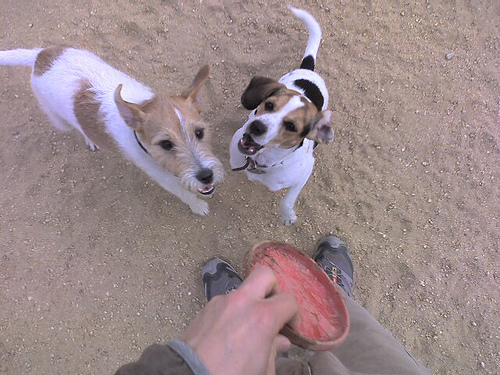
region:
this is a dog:
[200, 0, 360, 232]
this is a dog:
[3, 38, 238, 230]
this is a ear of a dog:
[308, 119, 344, 150]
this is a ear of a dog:
[228, 65, 280, 111]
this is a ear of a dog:
[171, 65, 228, 108]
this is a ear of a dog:
[103, 84, 150, 134]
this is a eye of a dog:
[188, 119, 212, 141]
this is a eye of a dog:
[150, 113, 182, 165]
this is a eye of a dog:
[283, 117, 298, 146]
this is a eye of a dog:
[262, 101, 279, 113]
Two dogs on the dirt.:
[1, 24, 336, 225]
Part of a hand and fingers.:
[175, 263, 300, 374]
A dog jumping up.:
[227, 4, 341, 228]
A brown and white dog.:
[1, 43, 228, 216]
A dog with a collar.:
[229, 5, 341, 227]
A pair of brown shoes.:
[200, 235, 355, 306]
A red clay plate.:
[239, 237, 351, 351]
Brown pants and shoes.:
[198, 235, 430, 374]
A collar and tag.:
[232, 155, 267, 175]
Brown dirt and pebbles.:
[3, 2, 498, 371]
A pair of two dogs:
[1, 5, 335, 226]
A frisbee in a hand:
[175, 239, 352, 373]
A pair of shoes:
[200, 231, 357, 304]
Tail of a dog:
[284, 2, 325, 67]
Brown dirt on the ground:
[1, 0, 498, 373]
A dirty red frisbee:
[243, 238, 352, 353]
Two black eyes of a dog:
[157, 123, 210, 154]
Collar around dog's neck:
[230, 136, 309, 180]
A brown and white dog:
[0, 41, 226, 220]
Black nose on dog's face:
[244, 111, 269, 141]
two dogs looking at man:
[30, 41, 344, 214]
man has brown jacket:
[140, 332, 204, 367]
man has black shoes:
[303, 224, 365, 291]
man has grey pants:
[337, 285, 432, 372]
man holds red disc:
[262, 238, 389, 353]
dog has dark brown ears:
[247, 57, 336, 149]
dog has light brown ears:
[117, 67, 215, 135]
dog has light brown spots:
[23, 42, 173, 187]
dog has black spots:
[292, 45, 330, 112]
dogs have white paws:
[229, 175, 327, 240]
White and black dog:
[214, 14, 374, 241]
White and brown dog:
[14, 12, 234, 206]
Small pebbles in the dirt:
[427, 211, 467, 317]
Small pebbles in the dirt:
[425, 326, 487, 371]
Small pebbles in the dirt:
[61, 327, 106, 373]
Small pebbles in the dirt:
[18, 286, 140, 362]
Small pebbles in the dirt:
[51, 191, 173, 286]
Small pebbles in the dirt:
[119, 17, 168, 54]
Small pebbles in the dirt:
[193, 22, 258, 69]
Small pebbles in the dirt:
[355, 12, 498, 326]